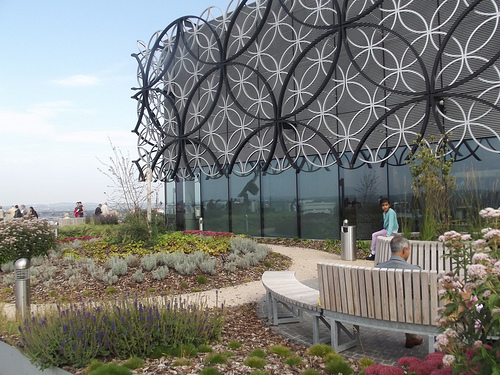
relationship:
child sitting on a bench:
[369, 198, 391, 262] [372, 227, 492, 275]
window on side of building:
[261, 162, 301, 236] [131, 1, 499, 238]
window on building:
[261, 162, 301, 236] [131, 1, 499, 238]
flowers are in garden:
[2, 215, 56, 262] [1, 203, 292, 295]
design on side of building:
[130, 1, 499, 182] [131, 1, 499, 238]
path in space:
[1, 238, 337, 326] [9, 272, 259, 333]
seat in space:
[255, 260, 463, 361] [5, 328, 384, 358]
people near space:
[10, 204, 43, 219] [4, 219, 129, 245]